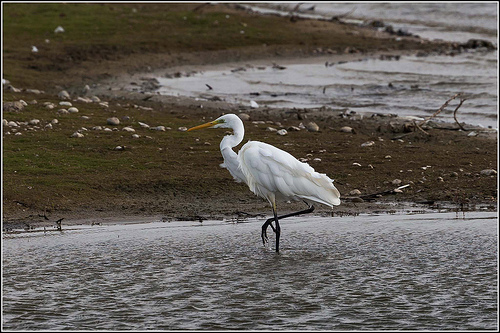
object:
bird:
[186, 112, 340, 253]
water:
[0, 206, 498, 333]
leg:
[268, 203, 282, 255]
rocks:
[359, 137, 380, 147]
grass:
[0, 0, 499, 225]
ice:
[314, 293, 336, 313]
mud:
[374, 198, 405, 210]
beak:
[184, 121, 215, 131]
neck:
[214, 128, 243, 165]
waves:
[0, 219, 499, 328]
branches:
[453, 93, 473, 129]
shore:
[0, 0, 499, 235]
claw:
[259, 218, 274, 245]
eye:
[210, 116, 226, 125]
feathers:
[240, 140, 344, 207]